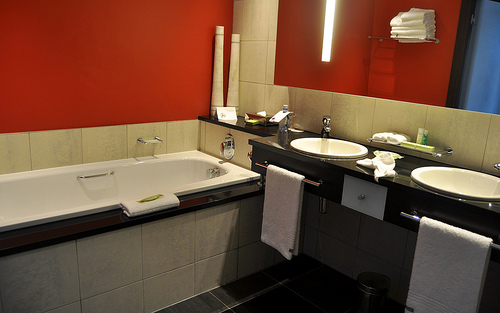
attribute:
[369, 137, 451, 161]
shelf — small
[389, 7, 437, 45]
towels — on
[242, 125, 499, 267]
sink cabinet — grey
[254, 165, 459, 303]
towels — white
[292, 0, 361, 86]
light — on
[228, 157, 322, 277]
towel — white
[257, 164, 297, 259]
towell — on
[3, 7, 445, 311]
bathroom — big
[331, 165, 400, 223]
drawer — on